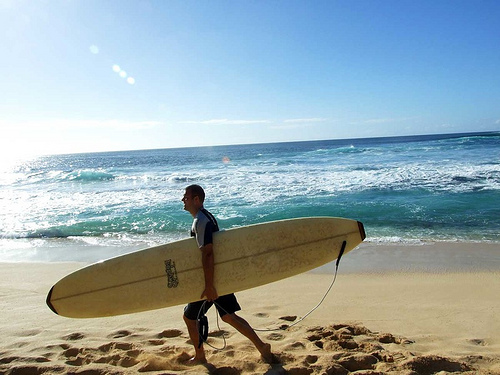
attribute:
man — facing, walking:
[178, 181, 273, 368]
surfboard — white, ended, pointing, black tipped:
[45, 212, 365, 318]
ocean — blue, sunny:
[0, 132, 499, 244]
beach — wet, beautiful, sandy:
[1, 240, 498, 374]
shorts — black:
[183, 293, 243, 321]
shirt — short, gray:
[187, 207, 219, 248]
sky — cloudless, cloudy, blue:
[1, 2, 499, 157]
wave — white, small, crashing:
[5, 166, 121, 188]